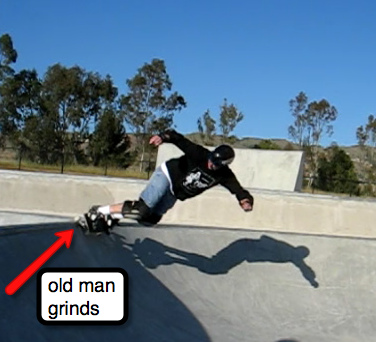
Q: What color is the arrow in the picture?
A: Red.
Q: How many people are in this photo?
A: One.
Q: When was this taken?
A: Daytime.